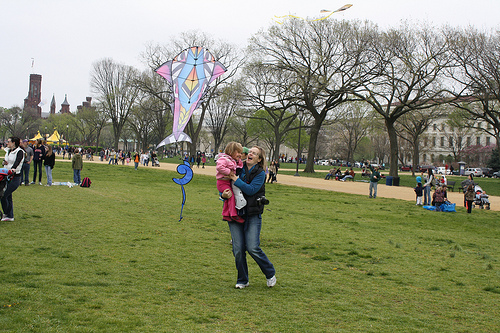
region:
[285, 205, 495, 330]
a section of green grass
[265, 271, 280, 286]
a woman's white tennis shoe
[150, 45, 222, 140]
a large colorful kite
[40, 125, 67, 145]
a large yellow tent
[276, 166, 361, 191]
a brown dirt road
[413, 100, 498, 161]
part of a white building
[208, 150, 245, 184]
a girl's pink coat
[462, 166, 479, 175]
part of a white vehicle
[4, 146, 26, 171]
a woman's white vest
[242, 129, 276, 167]
head of a person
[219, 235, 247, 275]
leg of a person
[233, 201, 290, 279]
leg of a person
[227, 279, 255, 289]
feet of a person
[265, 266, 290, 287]
feet of a person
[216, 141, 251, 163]
head of a person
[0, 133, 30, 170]
head of a person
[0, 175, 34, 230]
leg of a person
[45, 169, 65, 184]
leg of a person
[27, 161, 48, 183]
leg of a person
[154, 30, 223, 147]
Multi color kite in the sky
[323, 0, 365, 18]
yellow kite in the sky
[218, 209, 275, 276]
woman wearing blue jeans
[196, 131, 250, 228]
woman holding a small child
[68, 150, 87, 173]
person wearing a green jacket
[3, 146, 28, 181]
woman wearing a white vest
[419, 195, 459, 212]
blue backpack on the ground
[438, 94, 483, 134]
Leaves on a tree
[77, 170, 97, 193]
backpack on the round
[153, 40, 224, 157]
The kite is fish.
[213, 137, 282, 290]
The woman is holding a little girl.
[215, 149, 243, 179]
The girl's coat is pink.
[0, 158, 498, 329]
The grass is green.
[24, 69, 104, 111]
There are buildings in the background.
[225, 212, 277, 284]
She is wearing jeans.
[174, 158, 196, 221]
The kite's tail is blue.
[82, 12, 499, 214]
The trees don't have leaves.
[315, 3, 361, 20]
The kite is flying.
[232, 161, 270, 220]
The woman's kite was blue.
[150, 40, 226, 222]
a kite in the sky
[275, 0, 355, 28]
a kite in the sky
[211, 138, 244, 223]
a child in a pink jacket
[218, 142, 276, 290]
a woman in a blue shirt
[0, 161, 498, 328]
A large grassy field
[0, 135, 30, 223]
a woman in a black shirt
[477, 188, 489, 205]
a toddler in a stroller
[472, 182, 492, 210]
a stroller on the sidewalk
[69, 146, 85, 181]
a person in a green jacket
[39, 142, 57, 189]
a girl in a black jacket